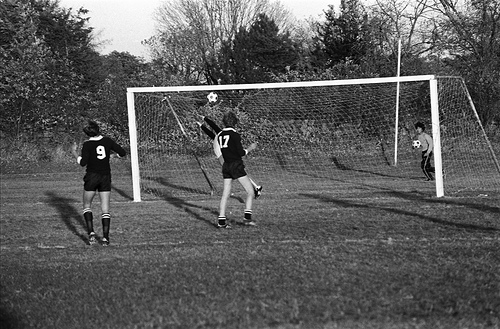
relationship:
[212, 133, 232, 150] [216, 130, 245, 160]
17 on jersey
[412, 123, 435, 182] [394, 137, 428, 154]
boy holding ball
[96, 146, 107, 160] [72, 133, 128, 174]
9 on shirt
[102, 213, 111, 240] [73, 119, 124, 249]
sock on player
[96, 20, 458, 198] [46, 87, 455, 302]
pole in ground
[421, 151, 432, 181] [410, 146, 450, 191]
stripe on pants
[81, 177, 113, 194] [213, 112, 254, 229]
shorts on boy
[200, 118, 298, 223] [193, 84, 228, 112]
goalie failing to stop ball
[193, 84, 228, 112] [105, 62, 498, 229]
ball going into net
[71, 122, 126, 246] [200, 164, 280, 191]
boy wearing shorts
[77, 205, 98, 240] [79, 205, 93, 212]
sock with stripe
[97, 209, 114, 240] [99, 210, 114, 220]
sock with stripe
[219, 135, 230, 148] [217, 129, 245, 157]
17 on shirt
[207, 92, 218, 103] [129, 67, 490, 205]
ball in net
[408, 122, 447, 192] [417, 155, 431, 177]
boy in pants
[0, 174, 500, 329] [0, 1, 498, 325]
grass on soccer field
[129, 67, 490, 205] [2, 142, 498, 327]
net on ground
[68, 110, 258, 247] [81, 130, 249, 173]
two players in black shirts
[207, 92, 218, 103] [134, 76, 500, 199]
ball into net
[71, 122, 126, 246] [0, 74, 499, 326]
boy on soccer field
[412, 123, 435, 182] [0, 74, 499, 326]
boy on soccer field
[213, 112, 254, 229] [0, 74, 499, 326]
boy on soccer field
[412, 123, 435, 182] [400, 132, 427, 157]
boy carrying ball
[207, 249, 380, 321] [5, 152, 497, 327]
grass in field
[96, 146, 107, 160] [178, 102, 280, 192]
9 on shirt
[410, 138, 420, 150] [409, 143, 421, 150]
ball in hand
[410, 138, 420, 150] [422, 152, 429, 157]
ball in hand